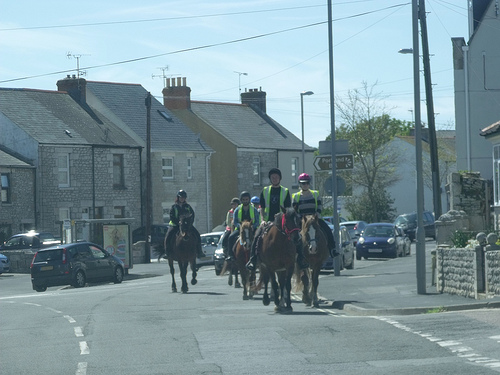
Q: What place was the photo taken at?
A: It was taken at the street.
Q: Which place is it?
A: It is a street.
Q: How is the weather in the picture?
A: It is clear.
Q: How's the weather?
A: It is clear.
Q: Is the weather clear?
A: Yes, it is clear.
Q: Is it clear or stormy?
A: It is clear.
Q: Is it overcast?
A: No, it is clear.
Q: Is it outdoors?
A: Yes, it is outdoors.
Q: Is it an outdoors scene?
A: Yes, it is outdoors.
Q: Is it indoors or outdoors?
A: It is outdoors.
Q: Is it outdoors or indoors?
A: It is outdoors.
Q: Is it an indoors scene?
A: No, it is outdoors.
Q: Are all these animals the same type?
A: Yes, all the animals are horses.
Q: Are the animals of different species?
A: No, all the animals are horses.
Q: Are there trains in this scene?
A: No, there are no trains.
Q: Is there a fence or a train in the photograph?
A: No, there are no trains or fences.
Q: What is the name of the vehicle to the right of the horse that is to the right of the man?
A: The vehicle is a car.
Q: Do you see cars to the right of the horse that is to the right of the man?
A: Yes, there is a car to the right of the horse.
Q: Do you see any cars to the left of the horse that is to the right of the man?
A: No, the car is to the right of the horse.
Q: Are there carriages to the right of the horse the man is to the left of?
A: No, there is a car to the right of the horse.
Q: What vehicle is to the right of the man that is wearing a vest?
A: The vehicle is a car.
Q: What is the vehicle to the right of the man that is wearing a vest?
A: The vehicle is a car.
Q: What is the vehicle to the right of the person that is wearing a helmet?
A: The vehicle is a car.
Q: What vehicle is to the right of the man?
A: The vehicle is a car.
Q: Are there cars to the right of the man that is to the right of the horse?
A: Yes, there is a car to the right of the man.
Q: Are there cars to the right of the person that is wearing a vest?
A: Yes, there is a car to the right of the man.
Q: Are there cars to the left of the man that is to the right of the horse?
A: No, the car is to the right of the man.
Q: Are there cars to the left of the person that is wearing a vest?
A: No, the car is to the right of the man.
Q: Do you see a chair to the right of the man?
A: No, there is a car to the right of the man.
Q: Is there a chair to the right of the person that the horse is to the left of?
A: No, there is a car to the right of the man.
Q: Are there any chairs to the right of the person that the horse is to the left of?
A: No, there is a car to the right of the man.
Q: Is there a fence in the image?
A: No, there are no fences.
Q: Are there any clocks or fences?
A: No, there are no fences or clocks.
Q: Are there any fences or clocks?
A: No, there are no fences or clocks.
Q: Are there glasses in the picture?
A: No, there are no glasses.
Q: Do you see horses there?
A: Yes, there is a horse.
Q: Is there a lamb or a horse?
A: Yes, there is a horse.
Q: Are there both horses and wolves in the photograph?
A: No, there is a horse but no wolves.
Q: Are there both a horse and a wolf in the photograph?
A: No, there is a horse but no wolves.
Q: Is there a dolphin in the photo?
A: No, there are no dolphins.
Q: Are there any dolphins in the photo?
A: No, there are no dolphins.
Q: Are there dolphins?
A: No, there are no dolphins.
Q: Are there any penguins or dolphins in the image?
A: No, there are no dolphins or penguins.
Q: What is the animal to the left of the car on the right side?
A: The animal is a horse.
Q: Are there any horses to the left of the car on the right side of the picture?
A: Yes, there is a horse to the left of the car.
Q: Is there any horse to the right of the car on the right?
A: No, the horse is to the left of the car.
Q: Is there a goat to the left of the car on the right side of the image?
A: No, there is a horse to the left of the car.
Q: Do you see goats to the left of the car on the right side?
A: No, there is a horse to the left of the car.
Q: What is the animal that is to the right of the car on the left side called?
A: The animal is a horse.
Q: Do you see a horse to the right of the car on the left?
A: Yes, there is a horse to the right of the car.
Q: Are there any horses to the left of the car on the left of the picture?
A: No, the horse is to the right of the car.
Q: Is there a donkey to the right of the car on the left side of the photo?
A: No, there is a horse to the right of the car.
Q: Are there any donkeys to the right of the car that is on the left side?
A: No, there is a horse to the right of the car.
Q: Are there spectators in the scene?
A: No, there are no spectators.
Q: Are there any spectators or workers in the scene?
A: No, there are no spectators or workers.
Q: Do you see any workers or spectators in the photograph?
A: No, there are no spectators or workers.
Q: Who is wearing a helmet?
A: The man is wearing a helmet.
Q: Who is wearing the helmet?
A: The man is wearing a helmet.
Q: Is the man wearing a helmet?
A: Yes, the man is wearing a helmet.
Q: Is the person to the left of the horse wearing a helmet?
A: Yes, the man is wearing a helmet.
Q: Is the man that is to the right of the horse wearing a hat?
A: No, the man is wearing a helmet.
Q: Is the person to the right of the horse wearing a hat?
A: No, the man is wearing a helmet.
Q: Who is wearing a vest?
A: The man is wearing a vest.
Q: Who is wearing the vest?
A: The man is wearing a vest.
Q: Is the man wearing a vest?
A: Yes, the man is wearing a vest.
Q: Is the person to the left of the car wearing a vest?
A: Yes, the man is wearing a vest.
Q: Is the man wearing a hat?
A: No, the man is wearing a vest.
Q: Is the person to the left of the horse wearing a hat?
A: No, the man is wearing a vest.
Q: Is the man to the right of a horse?
A: Yes, the man is to the right of a horse.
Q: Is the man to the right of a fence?
A: No, the man is to the right of a horse.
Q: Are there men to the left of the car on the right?
A: Yes, there is a man to the left of the car.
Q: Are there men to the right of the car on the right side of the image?
A: No, the man is to the left of the car.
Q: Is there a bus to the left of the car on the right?
A: No, there is a man to the left of the car.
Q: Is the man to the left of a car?
A: Yes, the man is to the left of a car.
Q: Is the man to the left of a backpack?
A: No, the man is to the left of a car.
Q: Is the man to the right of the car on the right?
A: No, the man is to the left of the car.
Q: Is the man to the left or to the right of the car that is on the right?
A: The man is to the left of the car.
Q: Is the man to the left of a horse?
A: No, the man is to the right of a horse.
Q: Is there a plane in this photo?
A: No, there are no airplanes.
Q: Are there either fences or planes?
A: No, there are no planes or fences.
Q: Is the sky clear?
A: Yes, the sky is clear.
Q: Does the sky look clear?
A: Yes, the sky is clear.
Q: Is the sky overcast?
A: No, the sky is clear.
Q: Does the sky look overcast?
A: No, the sky is clear.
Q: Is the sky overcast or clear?
A: The sky is clear.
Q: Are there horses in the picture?
A: Yes, there is a horse.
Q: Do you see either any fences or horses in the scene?
A: Yes, there is a horse.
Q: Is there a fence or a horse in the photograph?
A: Yes, there is a horse.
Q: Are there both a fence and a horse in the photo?
A: No, there is a horse but no fences.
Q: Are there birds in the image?
A: No, there are no birds.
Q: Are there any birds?
A: No, there are no birds.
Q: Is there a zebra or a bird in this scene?
A: No, there are no birds or zebras.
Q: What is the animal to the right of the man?
A: The animal is a horse.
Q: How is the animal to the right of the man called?
A: The animal is a horse.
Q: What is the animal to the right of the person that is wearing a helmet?
A: The animal is a horse.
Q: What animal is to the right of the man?
A: The animal is a horse.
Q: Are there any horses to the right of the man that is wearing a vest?
A: Yes, there is a horse to the right of the man.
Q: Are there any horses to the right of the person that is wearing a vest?
A: Yes, there is a horse to the right of the man.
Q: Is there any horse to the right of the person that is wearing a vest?
A: Yes, there is a horse to the right of the man.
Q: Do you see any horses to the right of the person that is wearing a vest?
A: Yes, there is a horse to the right of the man.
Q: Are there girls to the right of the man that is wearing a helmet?
A: No, there is a horse to the right of the man.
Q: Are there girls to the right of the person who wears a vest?
A: No, there is a horse to the right of the man.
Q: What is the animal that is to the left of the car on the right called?
A: The animal is a horse.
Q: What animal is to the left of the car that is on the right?
A: The animal is a horse.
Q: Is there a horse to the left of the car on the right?
A: Yes, there is a horse to the left of the car.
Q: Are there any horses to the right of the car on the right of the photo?
A: No, the horse is to the left of the car.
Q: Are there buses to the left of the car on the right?
A: No, there is a horse to the left of the car.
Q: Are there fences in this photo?
A: No, there are no fences.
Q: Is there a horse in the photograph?
A: Yes, there is a horse.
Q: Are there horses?
A: Yes, there is a horse.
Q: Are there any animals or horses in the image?
A: Yes, there is a horse.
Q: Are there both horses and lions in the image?
A: No, there is a horse but no lions.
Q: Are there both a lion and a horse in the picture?
A: No, there is a horse but no lions.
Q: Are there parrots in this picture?
A: No, there are no parrots.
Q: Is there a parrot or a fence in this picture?
A: No, there are no parrots or fences.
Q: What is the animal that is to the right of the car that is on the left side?
A: The animal is a horse.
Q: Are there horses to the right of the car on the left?
A: Yes, there is a horse to the right of the car.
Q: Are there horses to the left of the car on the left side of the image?
A: No, the horse is to the right of the car.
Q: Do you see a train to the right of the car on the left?
A: No, there is a horse to the right of the car.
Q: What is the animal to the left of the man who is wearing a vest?
A: The animal is a horse.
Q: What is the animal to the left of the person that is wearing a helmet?
A: The animal is a horse.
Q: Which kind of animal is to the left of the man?
A: The animal is a horse.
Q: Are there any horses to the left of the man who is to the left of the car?
A: Yes, there is a horse to the left of the man.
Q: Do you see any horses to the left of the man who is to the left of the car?
A: Yes, there is a horse to the left of the man.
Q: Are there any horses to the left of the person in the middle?
A: Yes, there is a horse to the left of the man.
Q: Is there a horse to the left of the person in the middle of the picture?
A: Yes, there is a horse to the left of the man.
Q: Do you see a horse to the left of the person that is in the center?
A: Yes, there is a horse to the left of the man.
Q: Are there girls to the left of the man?
A: No, there is a horse to the left of the man.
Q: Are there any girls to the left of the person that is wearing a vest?
A: No, there is a horse to the left of the man.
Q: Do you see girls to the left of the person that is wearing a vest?
A: No, there is a horse to the left of the man.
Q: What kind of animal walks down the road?
A: The animal is a horse.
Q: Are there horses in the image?
A: Yes, there is a horse.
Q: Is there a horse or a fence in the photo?
A: Yes, there is a horse.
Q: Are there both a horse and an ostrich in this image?
A: No, there is a horse but no ostriches.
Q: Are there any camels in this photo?
A: No, there are no camels.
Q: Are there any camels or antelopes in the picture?
A: No, there are no camels or antelopes.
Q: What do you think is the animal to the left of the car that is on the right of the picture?
A: The animal is a horse.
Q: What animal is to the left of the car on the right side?
A: The animal is a horse.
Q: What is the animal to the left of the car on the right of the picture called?
A: The animal is a horse.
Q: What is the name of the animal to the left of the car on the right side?
A: The animal is a horse.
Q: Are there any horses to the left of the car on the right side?
A: Yes, there is a horse to the left of the car.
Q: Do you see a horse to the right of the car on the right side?
A: No, the horse is to the left of the car.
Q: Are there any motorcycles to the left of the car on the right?
A: No, there is a horse to the left of the car.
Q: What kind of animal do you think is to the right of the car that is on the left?
A: The animal is a horse.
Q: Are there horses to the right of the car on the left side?
A: Yes, there is a horse to the right of the car.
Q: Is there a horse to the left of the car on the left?
A: No, the horse is to the right of the car.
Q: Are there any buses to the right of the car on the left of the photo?
A: No, there is a horse to the right of the car.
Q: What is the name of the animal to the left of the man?
A: The animal is a horse.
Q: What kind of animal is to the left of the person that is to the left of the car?
A: The animal is a horse.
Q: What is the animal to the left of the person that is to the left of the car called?
A: The animal is a horse.